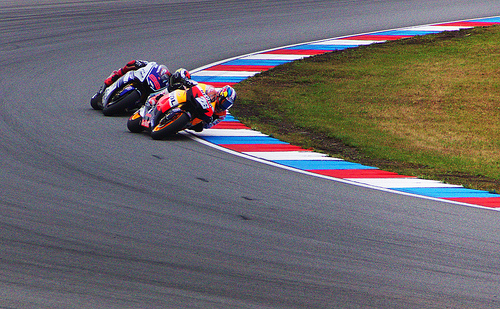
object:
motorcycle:
[127, 80, 237, 140]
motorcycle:
[90, 57, 173, 117]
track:
[0, 0, 396, 308]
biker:
[142, 80, 234, 133]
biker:
[99, 60, 192, 93]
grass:
[230, 26, 499, 195]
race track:
[0, 1, 289, 309]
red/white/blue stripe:
[176, 16, 500, 209]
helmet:
[170, 68, 192, 88]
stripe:
[319, 34, 387, 46]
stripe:
[346, 34, 410, 41]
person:
[104, 59, 195, 93]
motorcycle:
[90, 59, 216, 140]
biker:
[103, 59, 240, 132]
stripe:
[183, 14, 500, 215]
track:
[0, 67, 137, 265]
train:
[90, 58, 239, 139]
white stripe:
[344, 177, 465, 188]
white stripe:
[242, 151, 344, 160]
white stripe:
[185, 129, 269, 136]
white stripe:
[188, 70, 262, 76]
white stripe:
[239, 53, 315, 60]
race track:
[0, 0, 497, 309]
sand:
[367, 46, 500, 168]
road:
[0, 0, 499, 309]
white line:
[181, 14, 500, 212]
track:
[0, 0, 499, 309]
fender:
[117, 80, 145, 100]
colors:
[183, 14, 500, 212]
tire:
[150, 107, 192, 140]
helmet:
[217, 85, 237, 109]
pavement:
[0, 0, 499, 309]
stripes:
[253, 137, 310, 177]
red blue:
[186, 15, 498, 212]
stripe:
[392, 184, 497, 199]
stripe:
[388, 182, 498, 208]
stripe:
[276, 152, 409, 182]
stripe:
[201, 130, 303, 157]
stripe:
[206, 47, 295, 77]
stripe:
[260, 41, 366, 57]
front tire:
[102, 86, 142, 116]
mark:
[193, 175, 211, 182]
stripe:
[202, 60, 276, 73]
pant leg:
[104, 60, 134, 85]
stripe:
[368, 30, 437, 37]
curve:
[0, 0, 499, 309]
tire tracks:
[233, 26, 500, 194]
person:
[145, 80, 237, 133]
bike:
[127, 78, 237, 139]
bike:
[92, 57, 218, 140]